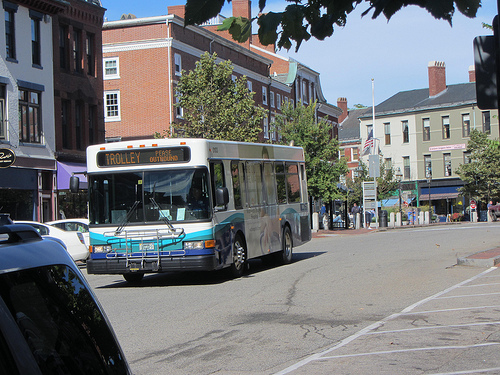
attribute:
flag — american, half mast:
[364, 130, 373, 149]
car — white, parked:
[1, 220, 89, 262]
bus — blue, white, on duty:
[87, 138, 313, 282]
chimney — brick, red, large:
[428, 60, 448, 99]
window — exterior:
[31, 92, 40, 104]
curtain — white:
[463, 114, 469, 122]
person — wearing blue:
[319, 203, 327, 220]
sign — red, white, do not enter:
[470, 200, 478, 210]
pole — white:
[370, 78, 379, 229]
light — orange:
[99, 147, 105, 152]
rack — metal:
[104, 229, 188, 269]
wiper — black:
[149, 197, 175, 233]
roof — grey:
[360, 82, 500, 119]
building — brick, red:
[103, 14, 271, 143]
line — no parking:
[273, 262, 500, 375]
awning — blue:
[419, 186, 461, 200]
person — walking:
[350, 203, 362, 230]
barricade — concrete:
[388, 212, 396, 229]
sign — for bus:
[361, 181, 379, 227]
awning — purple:
[56, 161, 87, 190]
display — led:
[96, 147, 190, 167]